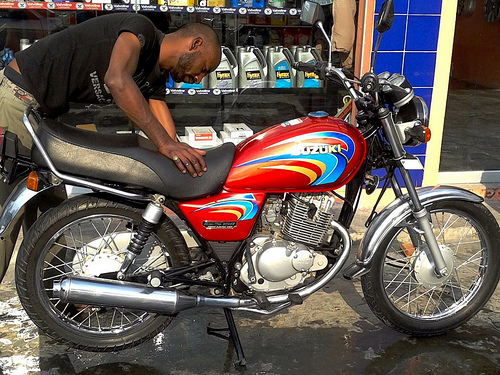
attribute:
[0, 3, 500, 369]
motorbike — red, cluster, cylinder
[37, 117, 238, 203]
seat — leather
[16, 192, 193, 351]
wheel — black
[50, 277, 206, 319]
pipe — exhaust, silver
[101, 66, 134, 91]
elbow — bent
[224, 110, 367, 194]
tank — red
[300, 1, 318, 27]
mirror — attached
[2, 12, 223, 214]
man — bent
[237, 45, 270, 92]
bottle — fluid